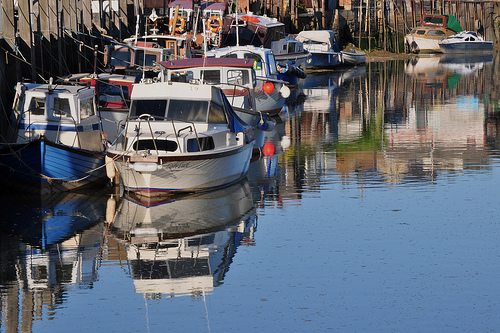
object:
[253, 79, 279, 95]
red light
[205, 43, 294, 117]
boat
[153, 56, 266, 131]
boat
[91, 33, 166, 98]
boat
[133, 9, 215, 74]
boat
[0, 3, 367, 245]
docks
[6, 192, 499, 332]
lake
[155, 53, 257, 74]
roof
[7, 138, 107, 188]
hull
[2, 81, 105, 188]
boat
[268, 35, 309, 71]
boat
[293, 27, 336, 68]
boat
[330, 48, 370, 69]
boat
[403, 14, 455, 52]
boat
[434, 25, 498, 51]
boat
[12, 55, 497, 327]
water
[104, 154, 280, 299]
reflection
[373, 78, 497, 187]
building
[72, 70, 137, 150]
boat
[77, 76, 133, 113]
red trim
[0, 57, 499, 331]
calm water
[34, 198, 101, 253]
reflection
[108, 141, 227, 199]
front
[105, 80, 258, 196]
boat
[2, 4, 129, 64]
posts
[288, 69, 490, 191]
reflection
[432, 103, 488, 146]
reflection